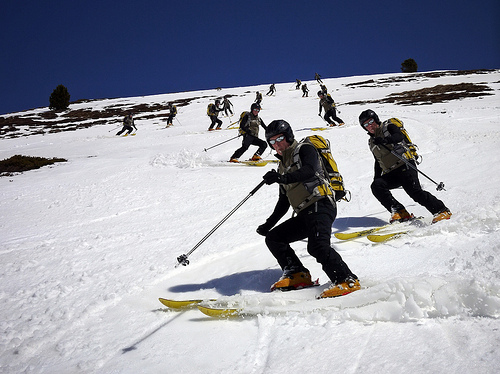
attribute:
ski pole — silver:
[175, 167, 276, 269]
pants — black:
[265, 192, 363, 284]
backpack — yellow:
[298, 132, 348, 202]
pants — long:
[260, 198, 354, 281]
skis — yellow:
[158, 295, 265, 317]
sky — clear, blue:
[0, 2, 500, 115]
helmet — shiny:
[262, 117, 299, 149]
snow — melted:
[39, 197, 76, 248]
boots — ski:
[271, 268, 363, 297]